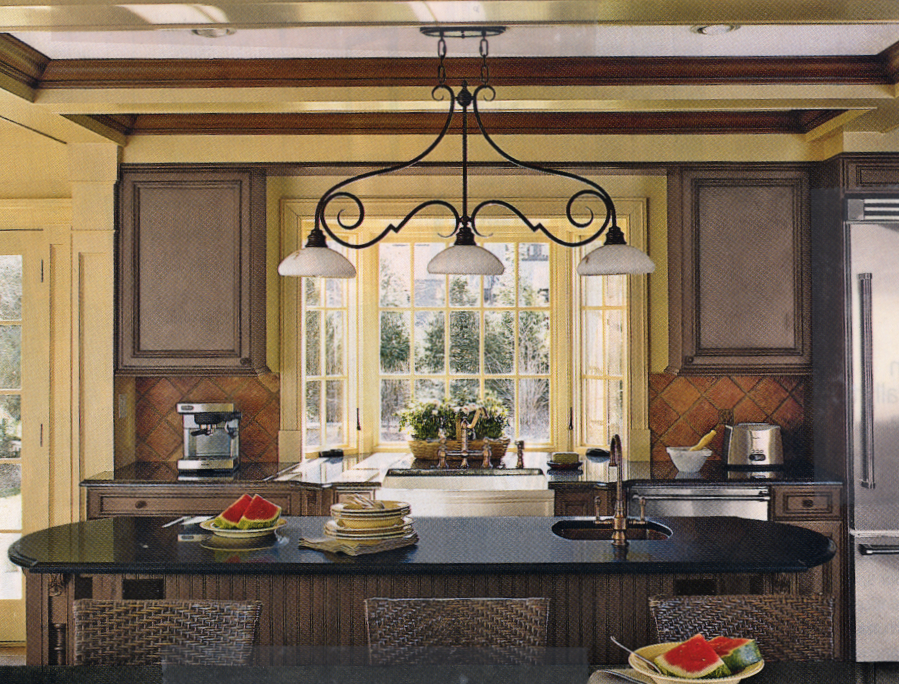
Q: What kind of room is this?
A: It is a kitchen.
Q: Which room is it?
A: It is a kitchen.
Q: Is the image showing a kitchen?
A: Yes, it is showing a kitchen.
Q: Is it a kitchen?
A: Yes, it is a kitchen.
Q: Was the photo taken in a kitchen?
A: Yes, it was taken in a kitchen.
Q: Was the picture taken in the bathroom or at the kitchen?
A: It was taken at the kitchen.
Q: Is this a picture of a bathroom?
A: No, the picture is showing a kitchen.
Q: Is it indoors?
A: Yes, it is indoors.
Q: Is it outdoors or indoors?
A: It is indoors.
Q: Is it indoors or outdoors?
A: It is indoors.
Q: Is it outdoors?
A: No, it is indoors.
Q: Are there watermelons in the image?
A: Yes, there is a watermelon.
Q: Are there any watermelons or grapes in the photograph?
A: Yes, there is a watermelon.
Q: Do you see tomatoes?
A: No, there are no tomatoes.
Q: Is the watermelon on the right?
A: Yes, the watermelon is on the right of the image.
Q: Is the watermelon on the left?
A: No, the watermelon is on the right of the image.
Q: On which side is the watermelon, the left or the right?
A: The watermelon is on the right of the image.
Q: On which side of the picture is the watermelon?
A: The watermelon is on the right of the image.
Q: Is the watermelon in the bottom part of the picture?
A: Yes, the watermelon is in the bottom of the image.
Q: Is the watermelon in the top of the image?
A: No, the watermelon is in the bottom of the image.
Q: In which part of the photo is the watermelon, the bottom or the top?
A: The watermelon is in the bottom of the image.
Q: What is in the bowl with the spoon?
A: The watermelon is in the bowl.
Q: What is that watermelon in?
A: The watermelon is in the bowl.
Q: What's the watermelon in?
A: The watermelon is in the bowl.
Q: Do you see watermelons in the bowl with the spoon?
A: Yes, there is a watermelon in the bowl.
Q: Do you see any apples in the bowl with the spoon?
A: No, there is a watermelon in the bowl.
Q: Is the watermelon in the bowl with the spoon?
A: Yes, the watermelon is in the bowl.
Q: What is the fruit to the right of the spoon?
A: The fruit is a watermelon.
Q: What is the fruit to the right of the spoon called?
A: The fruit is a watermelon.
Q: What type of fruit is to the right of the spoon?
A: The fruit is a watermelon.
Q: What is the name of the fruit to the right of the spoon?
A: The fruit is a watermelon.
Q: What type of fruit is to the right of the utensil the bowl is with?
A: The fruit is a watermelon.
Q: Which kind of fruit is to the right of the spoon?
A: The fruit is a watermelon.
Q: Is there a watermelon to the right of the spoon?
A: Yes, there is a watermelon to the right of the spoon.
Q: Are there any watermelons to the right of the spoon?
A: Yes, there is a watermelon to the right of the spoon.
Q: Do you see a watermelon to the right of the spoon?
A: Yes, there is a watermelon to the right of the spoon.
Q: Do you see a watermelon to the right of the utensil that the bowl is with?
A: Yes, there is a watermelon to the right of the spoon.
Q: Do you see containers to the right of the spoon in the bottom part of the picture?
A: No, there is a watermelon to the right of the spoon.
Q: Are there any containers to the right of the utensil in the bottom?
A: No, there is a watermelon to the right of the spoon.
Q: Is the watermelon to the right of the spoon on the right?
A: Yes, the watermelon is to the right of the spoon.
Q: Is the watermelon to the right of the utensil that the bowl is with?
A: Yes, the watermelon is to the right of the spoon.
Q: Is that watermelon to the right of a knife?
A: No, the watermelon is to the right of the spoon.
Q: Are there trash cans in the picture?
A: No, there are no trash cans.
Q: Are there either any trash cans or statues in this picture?
A: No, there are no trash cans or statues.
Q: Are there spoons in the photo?
A: Yes, there is a spoon.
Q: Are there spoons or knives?
A: Yes, there is a spoon.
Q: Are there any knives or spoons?
A: Yes, there is a spoon.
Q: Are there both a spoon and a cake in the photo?
A: No, there is a spoon but no cakes.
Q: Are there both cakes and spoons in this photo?
A: No, there is a spoon but no cakes.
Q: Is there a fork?
A: No, there are no forks.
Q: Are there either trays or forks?
A: No, there are no forks or trays.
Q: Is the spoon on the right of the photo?
A: Yes, the spoon is on the right of the image.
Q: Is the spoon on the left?
A: No, the spoon is on the right of the image.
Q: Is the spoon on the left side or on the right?
A: The spoon is on the right of the image.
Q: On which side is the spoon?
A: The spoon is on the right of the image.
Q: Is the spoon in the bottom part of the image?
A: Yes, the spoon is in the bottom of the image.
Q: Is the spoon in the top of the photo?
A: No, the spoon is in the bottom of the image.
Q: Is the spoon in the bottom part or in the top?
A: The spoon is in the bottom of the image.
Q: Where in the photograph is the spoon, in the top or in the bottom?
A: The spoon is in the bottom of the image.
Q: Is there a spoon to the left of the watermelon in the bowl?
A: Yes, there is a spoon to the left of the watermelon.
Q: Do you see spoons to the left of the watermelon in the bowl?
A: Yes, there is a spoon to the left of the watermelon.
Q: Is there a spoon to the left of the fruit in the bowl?
A: Yes, there is a spoon to the left of the watermelon.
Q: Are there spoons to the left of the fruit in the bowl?
A: Yes, there is a spoon to the left of the watermelon.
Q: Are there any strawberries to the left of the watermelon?
A: No, there is a spoon to the left of the watermelon.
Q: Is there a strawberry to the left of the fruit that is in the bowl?
A: No, there is a spoon to the left of the watermelon.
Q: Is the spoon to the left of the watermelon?
A: Yes, the spoon is to the left of the watermelon.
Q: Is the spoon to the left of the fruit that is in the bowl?
A: Yes, the spoon is to the left of the watermelon.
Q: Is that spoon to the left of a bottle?
A: No, the spoon is to the left of the watermelon.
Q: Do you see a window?
A: Yes, there is a window.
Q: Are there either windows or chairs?
A: Yes, there is a window.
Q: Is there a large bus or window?
A: Yes, there is a large window.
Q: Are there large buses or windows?
A: Yes, there is a large window.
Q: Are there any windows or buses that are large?
A: Yes, the window is large.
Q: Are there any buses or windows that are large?
A: Yes, the window is large.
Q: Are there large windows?
A: Yes, there is a large window.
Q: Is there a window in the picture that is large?
A: Yes, there is a window that is large.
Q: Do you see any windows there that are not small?
A: Yes, there is a large window.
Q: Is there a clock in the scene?
A: No, there are no clocks.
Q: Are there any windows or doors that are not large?
A: No, there is a window but it is large.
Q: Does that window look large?
A: Yes, the window is large.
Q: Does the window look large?
A: Yes, the window is large.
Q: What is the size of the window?
A: The window is large.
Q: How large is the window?
A: The window is large.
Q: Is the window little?
A: No, the window is large.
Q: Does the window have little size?
A: No, the window is large.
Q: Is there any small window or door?
A: No, there is a window but it is large.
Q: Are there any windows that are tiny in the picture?
A: No, there is a window but it is large.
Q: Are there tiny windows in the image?
A: No, there is a window but it is large.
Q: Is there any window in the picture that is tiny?
A: No, there is a window but it is large.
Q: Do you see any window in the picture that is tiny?
A: No, there is a window but it is large.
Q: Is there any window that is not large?
A: No, there is a window but it is large.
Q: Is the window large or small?
A: The window is large.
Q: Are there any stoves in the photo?
A: No, there are no stoves.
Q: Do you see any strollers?
A: No, there are no strollers.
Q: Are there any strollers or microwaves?
A: No, there are no strollers or microwaves.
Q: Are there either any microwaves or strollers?
A: No, there are no strollers or microwaves.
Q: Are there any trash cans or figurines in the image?
A: No, there are no trash cans or figurines.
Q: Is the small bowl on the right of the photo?
A: Yes, the bowl is on the right of the image.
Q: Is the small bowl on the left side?
A: No, the bowl is on the right of the image.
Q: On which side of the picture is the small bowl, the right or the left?
A: The bowl is on the right of the image.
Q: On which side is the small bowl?
A: The bowl is on the right of the image.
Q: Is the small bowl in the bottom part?
A: Yes, the bowl is in the bottom of the image.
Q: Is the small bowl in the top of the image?
A: No, the bowl is in the bottom of the image.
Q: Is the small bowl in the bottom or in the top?
A: The bowl is in the bottom of the image.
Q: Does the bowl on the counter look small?
A: Yes, the bowl is small.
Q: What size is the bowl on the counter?
A: The bowl is small.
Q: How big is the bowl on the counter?
A: The bowl is small.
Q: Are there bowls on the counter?
A: Yes, there is a bowl on the counter.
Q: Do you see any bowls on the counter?
A: Yes, there is a bowl on the counter.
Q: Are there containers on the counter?
A: No, there is a bowl on the counter.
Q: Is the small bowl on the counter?
A: Yes, the bowl is on the counter.